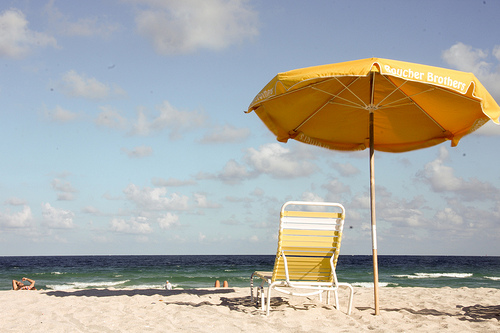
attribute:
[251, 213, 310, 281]
chair — white, yellow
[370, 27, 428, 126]
umbrella — yellow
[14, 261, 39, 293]
person — resting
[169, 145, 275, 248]
sky — clouds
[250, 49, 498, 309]
umbrella — yellow, beach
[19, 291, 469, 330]
beach — waterfront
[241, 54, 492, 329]
umbrella — yellow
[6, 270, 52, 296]
person — sunbathing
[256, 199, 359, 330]
chair — yellow, white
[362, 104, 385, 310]
umbrella pole — wood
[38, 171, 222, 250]
clouds — white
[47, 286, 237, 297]
shadow — umbrella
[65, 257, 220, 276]
water — green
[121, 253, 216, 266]
water — blue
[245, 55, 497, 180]
umbrella — yellow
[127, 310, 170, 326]
sand — brown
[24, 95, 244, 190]
sky — blue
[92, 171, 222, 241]
clouds — white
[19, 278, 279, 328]
sand — beige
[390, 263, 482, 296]
caps — white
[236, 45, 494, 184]
umbrella — yellow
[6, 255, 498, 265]
water — dark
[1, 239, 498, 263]
line — horizon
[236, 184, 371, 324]
chair — yellow, white, beach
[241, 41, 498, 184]
parasol — beach, yellow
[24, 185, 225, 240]
clouds — scattered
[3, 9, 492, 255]
sky — pale blue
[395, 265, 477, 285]
waves — gentle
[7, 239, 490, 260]
horizon — blue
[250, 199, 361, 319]
chair — yellow, white, beach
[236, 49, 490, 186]
parasol — beach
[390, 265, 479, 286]
foam — white